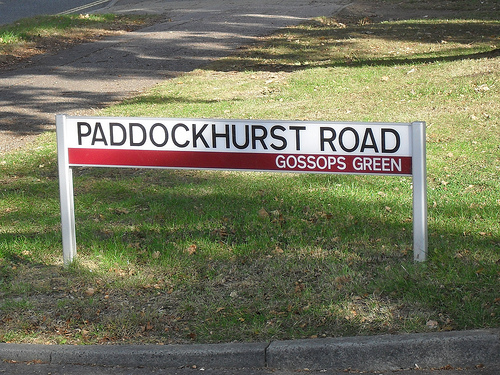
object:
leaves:
[133, 317, 167, 336]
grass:
[4, 4, 491, 342]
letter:
[91, 122, 108, 146]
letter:
[104, 122, 127, 147]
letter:
[128, 122, 147, 147]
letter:
[149, 122, 169, 147]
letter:
[171, 122, 190, 148]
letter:
[191, 123, 211, 148]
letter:
[211, 124, 230, 149]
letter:
[231, 124, 250, 150]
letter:
[251, 125, 269, 150]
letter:
[271, 125, 287, 150]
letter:
[319, 126, 336, 151]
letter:
[338, 126, 359, 152]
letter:
[360, 128, 379, 153]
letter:
[381, 128, 401, 153]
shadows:
[0, 0, 500, 133]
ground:
[0, 17, 496, 375]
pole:
[410, 121, 430, 266]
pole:
[54, 115, 77, 268]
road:
[3, 7, 366, 179]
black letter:
[288, 125, 308, 150]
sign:
[65, 114, 414, 177]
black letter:
[251, 124, 268, 150]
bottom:
[268, 156, 405, 172]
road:
[319, 126, 401, 154]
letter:
[76, 121, 91, 144]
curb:
[1, 329, 499, 373]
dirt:
[337, 0, 391, 21]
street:
[0, 325, 499, 373]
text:
[353, 157, 402, 172]